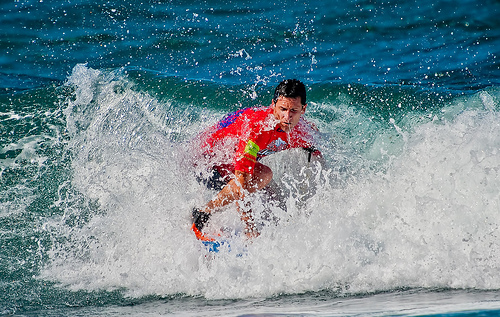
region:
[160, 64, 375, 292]
Man surfing in the ocean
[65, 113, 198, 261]
The water is splashing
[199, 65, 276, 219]
Man is wearing a wet suit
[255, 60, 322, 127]
Man has short dark hair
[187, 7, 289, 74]
Water splashing into the air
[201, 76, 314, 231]
The man has short sleeves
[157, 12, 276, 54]
The ocean is flat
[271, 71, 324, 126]
The man has short hair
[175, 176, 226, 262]
Man wearing ski shoes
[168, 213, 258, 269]
Man on a surfboard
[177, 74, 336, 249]
surfer riding a foamy wave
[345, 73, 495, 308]
large wave crashing at the shore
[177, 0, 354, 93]
water droplets spraying off crashing wave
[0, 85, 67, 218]
foamy water near crashing wave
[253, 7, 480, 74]
water droplets sparkling in the sun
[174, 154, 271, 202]
black shorts on a surfer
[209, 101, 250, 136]
blue design on the back of a red shirt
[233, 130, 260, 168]
yellow rectangle with black lettering on sleeve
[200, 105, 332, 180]
red shirt of a surfer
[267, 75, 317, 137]
man's head with black hair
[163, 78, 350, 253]
man crouching on surfboard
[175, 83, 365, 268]
man riding small wave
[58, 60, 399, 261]
wave splashing against water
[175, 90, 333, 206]
man wearing red wet suit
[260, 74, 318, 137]
man has brown hair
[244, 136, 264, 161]
yellow patch on red shirt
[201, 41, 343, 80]
blue green water in ocean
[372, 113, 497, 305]
wave creating white mist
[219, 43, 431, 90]
choppy portion of water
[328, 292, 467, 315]
shallow portion of water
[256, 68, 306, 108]
man's hair is black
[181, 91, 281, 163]
man's shirt is red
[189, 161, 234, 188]
man's short are black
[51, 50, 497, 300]
waves surrounding the man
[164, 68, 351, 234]
the man is wet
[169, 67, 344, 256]
the man is surfing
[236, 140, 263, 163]
green patch on shirt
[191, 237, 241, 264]
the part is blue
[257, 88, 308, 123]
man's eyes are closed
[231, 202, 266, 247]
man's hand on surfboard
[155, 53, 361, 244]
man in the water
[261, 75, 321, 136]
head of the man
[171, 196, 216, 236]
foot of the man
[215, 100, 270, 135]
blue and red shirt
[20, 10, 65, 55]
water in the background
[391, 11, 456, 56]
ripples in the water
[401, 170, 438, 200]
white water under the man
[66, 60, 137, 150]
wave forming in the water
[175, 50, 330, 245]
man crouched in the water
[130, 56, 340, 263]
man surfing in the ocean